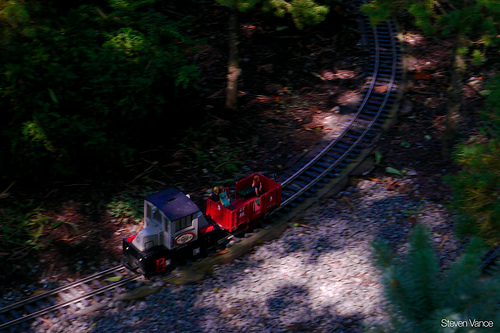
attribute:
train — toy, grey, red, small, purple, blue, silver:
[119, 165, 293, 269]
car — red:
[207, 173, 284, 238]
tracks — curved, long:
[5, 7, 428, 330]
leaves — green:
[6, 6, 206, 136]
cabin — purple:
[136, 185, 205, 253]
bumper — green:
[116, 243, 150, 283]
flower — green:
[49, 19, 155, 90]